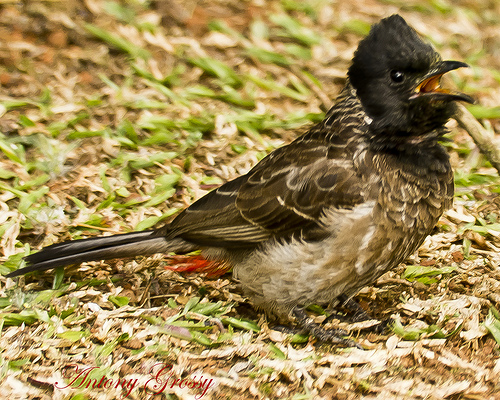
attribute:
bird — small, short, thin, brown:
[5, 13, 476, 348]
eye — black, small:
[388, 68, 407, 82]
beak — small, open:
[409, 60, 477, 106]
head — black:
[349, 13, 475, 139]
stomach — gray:
[297, 205, 400, 317]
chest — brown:
[377, 154, 456, 263]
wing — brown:
[153, 122, 359, 247]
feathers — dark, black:
[8, 229, 187, 277]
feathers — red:
[164, 254, 231, 280]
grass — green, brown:
[1, 2, 499, 398]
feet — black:
[290, 295, 386, 347]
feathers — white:
[279, 245, 365, 297]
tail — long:
[5, 226, 195, 280]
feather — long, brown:
[3, 234, 200, 279]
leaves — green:
[7, 37, 268, 400]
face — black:
[382, 41, 473, 122]